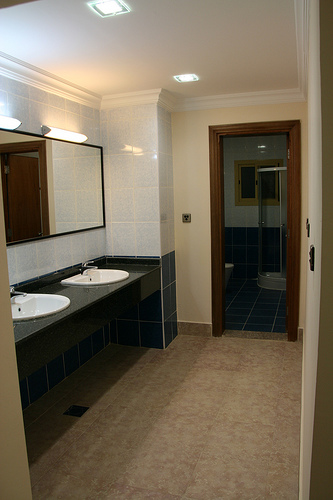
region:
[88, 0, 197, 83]
Lights on the ceiling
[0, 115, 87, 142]
Lights on the wall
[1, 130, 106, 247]
Mirror on the wall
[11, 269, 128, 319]
White sinks on the sink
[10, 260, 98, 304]
Faucets over the sinks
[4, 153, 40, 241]
Door reflection in the mirror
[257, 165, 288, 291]
Shower in the bathroom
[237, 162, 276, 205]
Window on the wall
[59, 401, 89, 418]
Drain in the floor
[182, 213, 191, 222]
Plug in on the wall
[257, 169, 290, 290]
A stand up shower.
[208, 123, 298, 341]
A brown wooden door frame.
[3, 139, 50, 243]
A reflection of a wooden door in the mirror.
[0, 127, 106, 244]
A large black framed mirror on the wall.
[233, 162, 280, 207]
A yellow framed window.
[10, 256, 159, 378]
Double sink area.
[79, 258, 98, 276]
A silver sink faucet.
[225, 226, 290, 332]
Blue tiles on the ground and part of the wall.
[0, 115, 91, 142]
Long tube lights above the mirror on the wall.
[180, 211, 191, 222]
A black and silver light switch.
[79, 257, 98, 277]
Silver faucet on white sink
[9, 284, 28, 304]
Silver faucet on white sink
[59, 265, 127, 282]
White sink on black counter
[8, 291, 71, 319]
White sink on black counter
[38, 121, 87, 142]
Light above large mirror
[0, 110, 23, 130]
Light above large mirror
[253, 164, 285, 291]
Shower stall next to window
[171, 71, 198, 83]
Recessed lighting on ceiling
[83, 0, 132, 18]
Recessed lighting on ceiling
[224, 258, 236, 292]
White toilet in front of shower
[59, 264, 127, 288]
white sink next to a white sink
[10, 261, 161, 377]
sink in a black counter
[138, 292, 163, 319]
black tile under counter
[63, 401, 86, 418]
dark drain in floor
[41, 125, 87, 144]
flourescent light above mirror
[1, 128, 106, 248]
large mirror above sinks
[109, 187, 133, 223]
white tile next to mirror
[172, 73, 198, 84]
square light on ceiling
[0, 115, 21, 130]
light is on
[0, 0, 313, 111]
white crown molding next to ceiling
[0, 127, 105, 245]
A large hanging bathroom mirror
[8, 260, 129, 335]
Two white bathroom sinks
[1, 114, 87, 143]
A set of the over the mirror lights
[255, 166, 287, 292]
A circular corner shower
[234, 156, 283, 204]
A yellow bathroom window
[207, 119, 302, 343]
A wooden doorway to a bathroom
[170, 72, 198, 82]
A square inset ceiling light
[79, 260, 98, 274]
A single lever bathroom faucet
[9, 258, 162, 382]
A black granite bathroom counter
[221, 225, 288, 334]
Dark blue bathroom tile on floor and walls